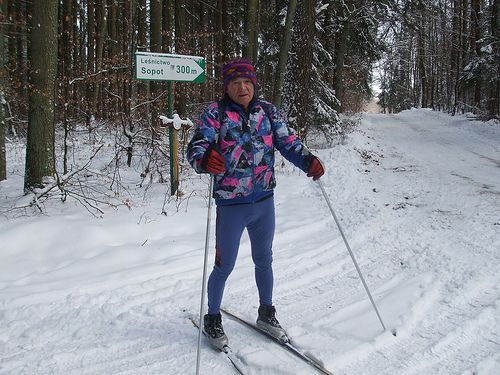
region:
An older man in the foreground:
[183, 42, 396, 374]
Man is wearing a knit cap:
[206, 51, 271, 129]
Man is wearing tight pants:
[197, 197, 296, 334]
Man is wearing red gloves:
[194, 136, 330, 193]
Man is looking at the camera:
[214, 50, 269, 122]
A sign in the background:
[126, 44, 209, 196]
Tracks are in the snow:
[0, 207, 489, 373]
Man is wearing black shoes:
[198, 291, 295, 346]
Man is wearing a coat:
[183, 94, 320, 210]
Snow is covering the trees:
[241, 2, 498, 147]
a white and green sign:
[131, 48, 207, 200]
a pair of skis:
[181, 303, 353, 373]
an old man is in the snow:
[196, 55, 326, 371]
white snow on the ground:
[3, 233, 173, 373]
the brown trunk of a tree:
[23, 5, 63, 197]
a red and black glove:
[194, 142, 227, 177]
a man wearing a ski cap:
[217, 52, 261, 112]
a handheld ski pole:
[191, 138, 220, 373]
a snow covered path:
[357, 100, 499, 347]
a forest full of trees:
[9, 5, 126, 195]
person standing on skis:
[128, 32, 382, 373]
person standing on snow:
[106, 56, 411, 370]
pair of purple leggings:
[189, 176, 296, 338]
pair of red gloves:
[200, 142, 351, 189]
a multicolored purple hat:
[213, 50, 270, 93]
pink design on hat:
[216, 54, 266, 86]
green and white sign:
[122, 39, 222, 116]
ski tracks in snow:
[83, 201, 380, 350]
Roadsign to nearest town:
[93, 26, 212, 253]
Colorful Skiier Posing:
[177, 54, 402, 369]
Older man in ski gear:
[166, 49, 403, 372]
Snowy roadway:
[310, 71, 497, 366]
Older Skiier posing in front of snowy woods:
[0, 1, 496, 363]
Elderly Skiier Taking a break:
[127, 42, 429, 372]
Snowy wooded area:
[0, 0, 498, 156]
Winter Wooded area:
[0, 2, 495, 198]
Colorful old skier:
[101, 51, 476, 371]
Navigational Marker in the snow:
[103, 18, 208, 253]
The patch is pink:
[221, 110, 244, 125]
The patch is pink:
[216, 133, 235, 150]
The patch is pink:
[231, 143, 245, 162]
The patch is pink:
[218, 173, 242, 188]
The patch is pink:
[261, 169, 274, 185]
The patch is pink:
[252, 164, 269, 176]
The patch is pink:
[261, 133, 276, 148]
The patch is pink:
[253, 110, 265, 132]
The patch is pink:
[282, 130, 298, 147]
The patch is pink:
[253, 104, 263, 116]